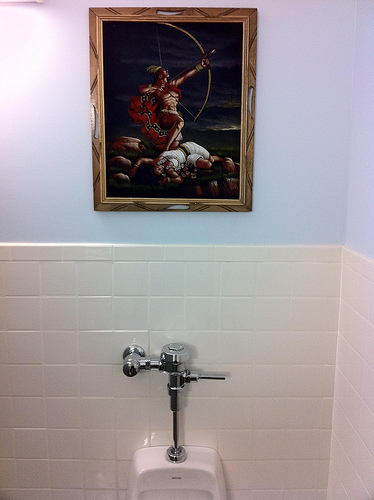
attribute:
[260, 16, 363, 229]
wall — blue, above tile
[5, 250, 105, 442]
tile — white, on wall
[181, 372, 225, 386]
handle — chrome, metal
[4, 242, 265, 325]
white tile — on wall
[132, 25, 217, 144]
man with bow — holding bow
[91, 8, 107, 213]
frame — brown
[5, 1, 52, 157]
cast of light — on wall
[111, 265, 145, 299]
tile — upon wall, piece of wall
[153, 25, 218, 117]
bow and arrow — in picture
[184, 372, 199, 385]
flushing handle — made of metal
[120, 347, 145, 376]
pipe — metal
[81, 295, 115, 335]
white tile — resting on wall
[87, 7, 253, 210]
picture — framed, hanging on wall, above toilet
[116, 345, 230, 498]
urinal — white, porcelain, attached to wall, on wall